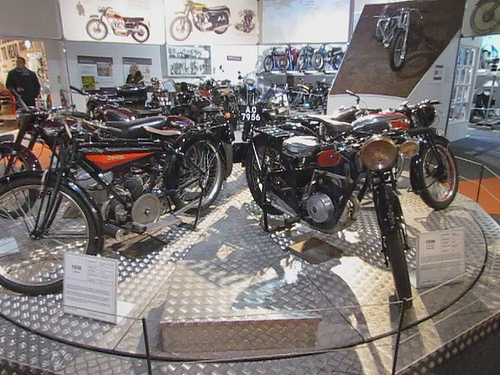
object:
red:
[87, 152, 151, 172]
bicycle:
[374, 6, 422, 72]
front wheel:
[384, 229, 413, 308]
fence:
[448, 43, 479, 125]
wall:
[0, 0, 392, 38]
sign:
[63, 251, 117, 323]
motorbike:
[279, 97, 459, 209]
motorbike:
[0, 88, 194, 220]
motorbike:
[69, 83, 161, 120]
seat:
[284, 135, 326, 157]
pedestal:
[157, 314, 317, 357]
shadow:
[164, 201, 391, 375]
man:
[5, 57, 41, 111]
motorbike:
[0, 108, 229, 296]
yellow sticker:
[59, 253, 133, 324]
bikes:
[244, 113, 440, 308]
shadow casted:
[168, 203, 290, 288]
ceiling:
[26, 2, 74, 38]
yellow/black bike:
[169, 0, 232, 42]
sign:
[51, 244, 136, 323]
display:
[0, 71, 497, 375]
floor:
[434, 132, 498, 216]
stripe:
[458, 155, 500, 201]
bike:
[264, 47, 291, 72]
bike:
[297, 47, 324, 71]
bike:
[310, 43, 345, 70]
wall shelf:
[267, 69, 337, 77]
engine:
[306, 182, 360, 234]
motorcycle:
[239, 112, 420, 310]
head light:
[358, 136, 400, 171]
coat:
[6, 67, 40, 100]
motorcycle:
[169, 0, 232, 41]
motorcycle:
[85, 6, 149, 43]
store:
[0, 0, 498, 374]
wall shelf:
[0, 157, 500, 370]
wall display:
[164, 0, 260, 47]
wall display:
[57, 1, 165, 47]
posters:
[55, 0, 261, 48]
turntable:
[0, 169, 498, 373]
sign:
[74, 51, 116, 94]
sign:
[123, 56, 153, 88]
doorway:
[0, 39, 50, 126]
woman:
[125, 63, 147, 105]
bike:
[226, 93, 444, 304]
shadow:
[407, 201, 496, 356]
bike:
[276, 99, 458, 211]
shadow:
[102, 213, 206, 287]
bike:
[0, 105, 233, 293]